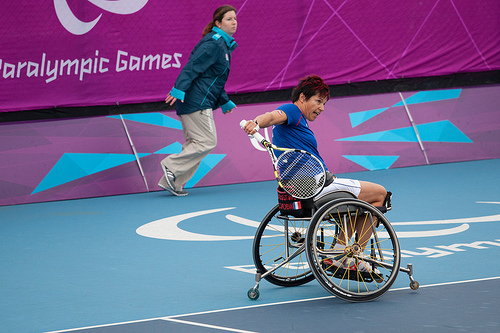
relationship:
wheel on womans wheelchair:
[307, 198, 400, 303] [250, 152, 420, 304]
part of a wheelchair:
[313, 188, 358, 215] [244, 173, 419, 303]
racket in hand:
[239, 115, 357, 207] [242, 119, 262, 139]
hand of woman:
[242, 119, 262, 139] [237, 73, 391, 282]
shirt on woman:
[225, 116, 305, 188] [255, 57, 397, 215]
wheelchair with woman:
[256, 171, 436, 281] [226, 61, 348, 165]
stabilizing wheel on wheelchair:
[244, 283, 266, 300] [241, 181, 421, 314]